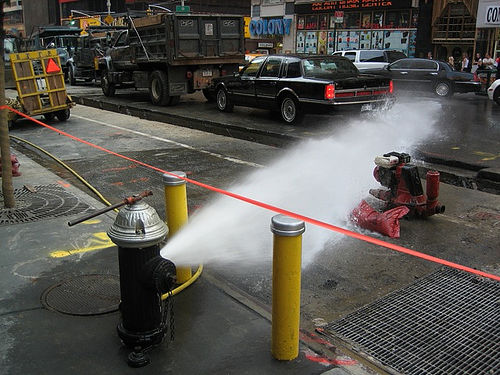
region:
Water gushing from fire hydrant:
[73, 132, 432, 327]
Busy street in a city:
[58, 0, 473, 367]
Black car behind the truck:
[206, 43, 414, 143]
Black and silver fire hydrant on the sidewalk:
[103, 190, 179, 355]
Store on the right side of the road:
[288, 5, 495, 91]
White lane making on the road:
[77, 109, 218, 168]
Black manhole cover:
[40, 265, 122, 327]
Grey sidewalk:
[2, 180, 97, 358]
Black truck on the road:
[98, 15, 233, 106]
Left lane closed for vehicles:
[4, 50, 409, 363]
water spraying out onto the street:
[152, 95, 444, 277]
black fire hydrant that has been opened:
[95, 196, 182, 353]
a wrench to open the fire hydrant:
[62, 178, 158, 238]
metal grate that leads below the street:
[315, 262, 498, 372]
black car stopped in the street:
[199, 46, 403, 132]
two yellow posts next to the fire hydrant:
[157, 168, 327, 367]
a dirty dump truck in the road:
[92, 7, 256, 106]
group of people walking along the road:
[415, 48, 498, 81]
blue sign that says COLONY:
[247, 13, 293, 40]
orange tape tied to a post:
[0, 98, 498, 288]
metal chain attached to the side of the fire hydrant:
[145, 278, 182, 351]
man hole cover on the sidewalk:
[38, 268, 130, 326]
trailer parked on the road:
[0, 48, 75, 125]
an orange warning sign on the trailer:
[42, 57, 63, 78]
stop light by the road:
[63, 4, 113, 34]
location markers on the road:
[48, 148, 364, 368]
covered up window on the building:
[292, 25, 415, 65]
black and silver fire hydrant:
[105, 196, 178, 359]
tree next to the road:
[0, 10, 39, 226]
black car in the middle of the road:
[202, 46, 399, 133]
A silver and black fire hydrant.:
[106, 196, 182, 356]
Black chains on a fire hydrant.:
[159, 277, 176, 344]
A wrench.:
[69, 188, 157, 229]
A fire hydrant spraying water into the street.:
[83, 97, 443, 366]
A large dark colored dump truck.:
[81, 14, 245, 114]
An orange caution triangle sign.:
[43, 59, 60, 73]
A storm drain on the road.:
[317, 261, 498, 373]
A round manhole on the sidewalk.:
[39, 262, 128, 315]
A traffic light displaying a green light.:
[65, 14, 77, 26]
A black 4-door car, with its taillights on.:
[206, 47, 404, 130]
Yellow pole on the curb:
[257, 236, 316, 367]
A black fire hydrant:
[98, 186, 192, 356]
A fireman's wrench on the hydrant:
[53, 183, 172, 221]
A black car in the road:
[201, 44, 398, 138]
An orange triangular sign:
[38, 56, 66, 79]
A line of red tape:
[5, 166, 490, 285]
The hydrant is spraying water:
[116, 173, 318, 298]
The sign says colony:
[242, 13, 302, 39]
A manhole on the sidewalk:
[47, 268, 122, 319]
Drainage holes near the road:
[15, 183, 95, 224]